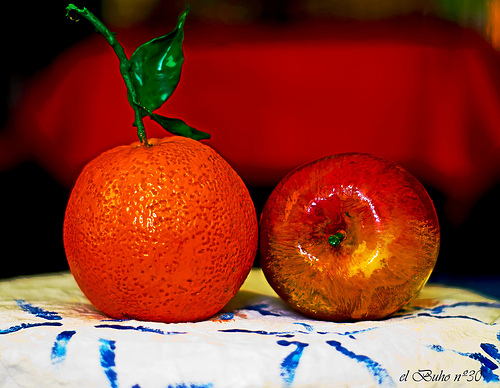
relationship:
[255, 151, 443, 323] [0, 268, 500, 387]
apple lying on top of cloth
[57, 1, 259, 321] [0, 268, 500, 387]
orange lying on top of cloth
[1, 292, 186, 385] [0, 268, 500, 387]
design adorning cloth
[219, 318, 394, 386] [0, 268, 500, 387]
design adorning cloth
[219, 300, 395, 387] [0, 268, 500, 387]
design adorning cloth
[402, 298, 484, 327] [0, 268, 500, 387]
design adorning cloth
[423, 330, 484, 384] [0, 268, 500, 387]
design adorning cloth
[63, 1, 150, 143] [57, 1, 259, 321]
stem attached to orange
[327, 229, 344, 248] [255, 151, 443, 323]
stem attached to apple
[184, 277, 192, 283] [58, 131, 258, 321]
dimple appearing on orange peel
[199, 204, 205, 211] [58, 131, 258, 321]
dimple appearing on orange peel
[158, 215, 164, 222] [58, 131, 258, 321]
dimple appearing on orange peel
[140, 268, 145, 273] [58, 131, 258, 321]
dimple appearing on orange peel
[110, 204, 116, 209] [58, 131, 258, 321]
dimple appearing on orange peel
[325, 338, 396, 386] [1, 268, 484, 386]
line adorning cloth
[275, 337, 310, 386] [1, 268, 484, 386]
line adorning cloth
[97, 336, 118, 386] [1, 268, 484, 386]
line adorning cloth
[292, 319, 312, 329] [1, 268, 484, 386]
line adorning cloth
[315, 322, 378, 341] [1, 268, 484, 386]
line adorning cloth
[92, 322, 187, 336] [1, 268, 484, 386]
line adorning cloth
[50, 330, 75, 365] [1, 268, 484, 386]
line adorning cloth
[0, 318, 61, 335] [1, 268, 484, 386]
line adorning cloth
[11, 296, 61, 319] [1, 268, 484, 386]
line adorning cloth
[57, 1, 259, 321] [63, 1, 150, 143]
orange attached to stem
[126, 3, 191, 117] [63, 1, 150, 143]
leaf attached to stem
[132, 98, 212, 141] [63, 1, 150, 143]
leaf attached to stem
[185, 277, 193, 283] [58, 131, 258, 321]
pore appearing on orange peel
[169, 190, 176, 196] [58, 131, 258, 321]
pore appearing on orange peel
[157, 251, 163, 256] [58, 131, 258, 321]
pore appearing on orange peel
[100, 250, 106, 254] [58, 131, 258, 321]
pore appearing on orange peel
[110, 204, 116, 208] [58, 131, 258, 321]
pore appearing on orange peel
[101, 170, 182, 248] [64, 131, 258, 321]
light reflecting on orange peel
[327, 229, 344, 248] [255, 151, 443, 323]
stem of apple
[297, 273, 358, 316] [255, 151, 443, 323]
part of apple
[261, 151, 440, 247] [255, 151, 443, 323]
part red of apple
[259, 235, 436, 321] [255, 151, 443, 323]
part yellow of apple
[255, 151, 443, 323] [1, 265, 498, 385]
apple on table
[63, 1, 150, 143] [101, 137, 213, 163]
stem on top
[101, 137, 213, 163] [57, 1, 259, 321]
top of orange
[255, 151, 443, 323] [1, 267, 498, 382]
apple on surface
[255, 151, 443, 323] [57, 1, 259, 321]
apple next to orange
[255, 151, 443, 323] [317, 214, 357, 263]
apple has top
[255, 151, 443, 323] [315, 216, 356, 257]
apple has top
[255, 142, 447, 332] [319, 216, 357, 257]
apple has top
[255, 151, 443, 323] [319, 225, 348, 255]
apple has top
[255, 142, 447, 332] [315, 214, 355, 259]
apple has top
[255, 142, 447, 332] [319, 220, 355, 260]
apple has top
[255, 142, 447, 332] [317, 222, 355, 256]
apple has top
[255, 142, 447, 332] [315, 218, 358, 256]
apple has top